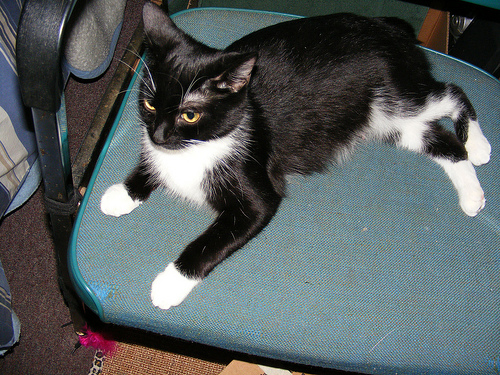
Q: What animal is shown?
A: A cat.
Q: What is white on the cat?
A: The paws.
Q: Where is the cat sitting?
A: A chair.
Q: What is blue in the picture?
A: The chair seat.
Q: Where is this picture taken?
A: An office.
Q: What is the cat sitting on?
A: A chair.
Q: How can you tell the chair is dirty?
A: It has dirt spots.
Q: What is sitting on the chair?
A: A cat.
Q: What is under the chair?
A: A rug.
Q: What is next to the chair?
A: A blue blanket.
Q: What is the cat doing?
A: Sitting on a dirty chair.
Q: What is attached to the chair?
A: A blue cushion.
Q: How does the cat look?
A: Relaxed.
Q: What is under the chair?
A: A purple fuzzball.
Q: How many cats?
A: 1.